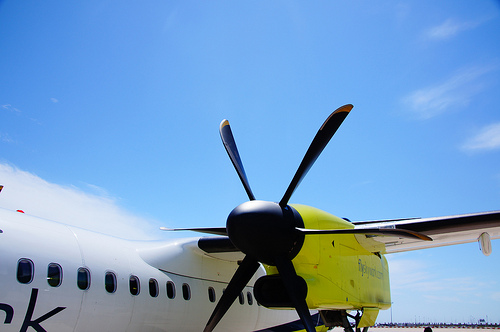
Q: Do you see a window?
A: Yes, there is a window.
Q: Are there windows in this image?
A: Yes, there is a window.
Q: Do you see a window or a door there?
A: Yes, there is a window.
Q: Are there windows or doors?
A: Yes, there is a window.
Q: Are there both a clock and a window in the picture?
A: No, there is a window but no clocks.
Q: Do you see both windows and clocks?
A: No, there is a window but no clocks.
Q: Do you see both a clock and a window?
A: No, there is a window but no clocks.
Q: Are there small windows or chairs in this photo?
A: Yes, there is a small window.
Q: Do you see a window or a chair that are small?
A: Yes, the window is small.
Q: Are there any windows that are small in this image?
A: Yes, there is a small window.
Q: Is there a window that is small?
A: Yes, there is a window that is small.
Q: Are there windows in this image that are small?
A: Yes, there is a window that is small.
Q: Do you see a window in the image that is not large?
A: Yes, there is a small window.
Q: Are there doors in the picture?
A: No, there are no doors.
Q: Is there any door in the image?
A: No, there are no doors.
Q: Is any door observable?
A: No, there are no doors.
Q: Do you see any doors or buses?
A: No, there are no doors or buses.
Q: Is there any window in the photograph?
A: Yes, there is a window.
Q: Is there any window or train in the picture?
A: Yes, there is a window.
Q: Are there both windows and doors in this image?
A: No, there is a window but no doors.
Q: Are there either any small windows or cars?
A: Yes, there is a small window.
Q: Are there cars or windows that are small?
A: Yes, the window is small.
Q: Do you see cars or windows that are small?
A: Yes, the window is small.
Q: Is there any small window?
A: Yes, there is a small window.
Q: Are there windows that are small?
A: Yes, there is a window that is small.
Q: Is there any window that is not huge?
A: Yes, there is a small window.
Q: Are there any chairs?
A: No, there are no chairs.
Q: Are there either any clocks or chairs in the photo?
A: No, there are no chairs or clocks.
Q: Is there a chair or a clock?
A: No, there are no chairs or clocks.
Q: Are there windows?
A: Yes, there is a window.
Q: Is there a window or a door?
A: Yes, there is a window.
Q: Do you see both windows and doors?
A: No, there is a window but no doors.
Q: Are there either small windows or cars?
A: Yes, there is a small window.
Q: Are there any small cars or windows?
A: Yes, there is a small window.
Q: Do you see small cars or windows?
A: Yes, there is a small window.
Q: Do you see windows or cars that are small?
A: Yes, the window is small.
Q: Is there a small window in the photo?
A: Yes, there is a small window.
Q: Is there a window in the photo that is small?
A: Yes, there is a window that is small.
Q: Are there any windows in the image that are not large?
A: Yes, there is a small window.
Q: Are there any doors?
A: No, there are no doors.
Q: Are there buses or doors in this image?
A: No, there are no doors or buses.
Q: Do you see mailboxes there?
A: No, there are no mailboxes.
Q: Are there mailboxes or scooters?
A: No, there are no mailboxes or scooters.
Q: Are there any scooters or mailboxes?
A: No, there are no mailboxes or scooters.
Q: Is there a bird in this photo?
A: No, there are no birds.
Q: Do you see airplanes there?
A: Yes, there is an airplane.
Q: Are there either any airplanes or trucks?
A: Yes, there is an airplane.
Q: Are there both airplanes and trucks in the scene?
A: No, there is an airplane but no trucks.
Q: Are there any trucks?
A: No, there are no trucks.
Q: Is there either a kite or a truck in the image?
A: No, there are no trucks or kites.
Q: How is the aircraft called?
A: The aircraft is an airplane.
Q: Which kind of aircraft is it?
A: The aircraft is an airplane.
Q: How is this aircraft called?
A: This is an airplane.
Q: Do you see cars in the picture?
A: No, there are no cars.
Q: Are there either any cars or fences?
A: No, there are no cars or fences.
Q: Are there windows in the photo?
A: Yes, there is a window.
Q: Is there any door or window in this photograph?
A: Yes, there is a window.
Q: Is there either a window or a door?
A: Yes, there is a window.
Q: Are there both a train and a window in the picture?
A: No, there is a window but no trains.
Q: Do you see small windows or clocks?
A: Yes, there is a small window.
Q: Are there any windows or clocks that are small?
A: Yes, the window is small.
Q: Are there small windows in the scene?
A: Yes, there is a small window.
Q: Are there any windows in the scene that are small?
A: Yes, there is a window that is small.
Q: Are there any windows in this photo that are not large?
A: Yes, there is a small window.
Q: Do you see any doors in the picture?
A: No, there are no doors.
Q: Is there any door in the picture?
A: No, there are no doors.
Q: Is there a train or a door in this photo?
A: No, there are no doors or trains.